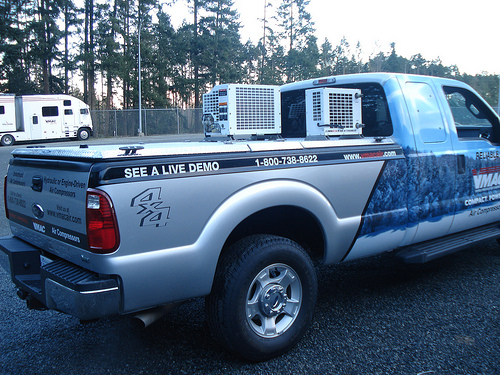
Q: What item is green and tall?
A: A tree.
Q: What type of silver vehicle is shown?
A: A truck.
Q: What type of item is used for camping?
A: A RV.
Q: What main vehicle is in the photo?
A: A 4x4 pickup truck.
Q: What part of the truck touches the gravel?
A: Rubber tires.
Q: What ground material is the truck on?
A: Gravel.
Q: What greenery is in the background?
A: Tall pine trees.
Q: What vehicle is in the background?
A: An RV camper.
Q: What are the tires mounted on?
A: Shiny rims.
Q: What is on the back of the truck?
A: A step bumper.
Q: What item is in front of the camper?
A: A metal light pole.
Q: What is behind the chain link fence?
A: Tall evergreen trees.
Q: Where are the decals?
A: On the truck.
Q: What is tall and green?
A: Trees.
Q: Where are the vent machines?
A: On the truck.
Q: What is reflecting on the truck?
A: Windows.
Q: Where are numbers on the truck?
A: On the back fender.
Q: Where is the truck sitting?
A: On the road.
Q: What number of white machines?
A: Two.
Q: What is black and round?
A: Tires.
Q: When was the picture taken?
A: Daytime.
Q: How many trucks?
A: One.